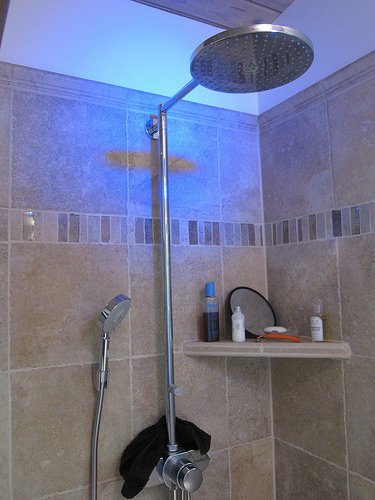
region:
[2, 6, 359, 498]
corner of a shower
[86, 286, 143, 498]
small movable shower head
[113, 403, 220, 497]
black washcloth on handle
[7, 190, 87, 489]
brown shower tile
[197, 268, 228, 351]
shower soap in the shower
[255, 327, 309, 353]
orange razor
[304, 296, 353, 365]
liquid shower soap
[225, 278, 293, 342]
small hand held mirror in the shower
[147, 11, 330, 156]
large shower head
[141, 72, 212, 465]
silver shower water pipes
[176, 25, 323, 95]
a large metal shower head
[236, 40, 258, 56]
tiny holes in the shower head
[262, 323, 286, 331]
a bar of white soap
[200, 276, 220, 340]
a plastic bottle of shampoo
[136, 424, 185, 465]
a black washcloth on the knob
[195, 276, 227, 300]
a blue top on the bottle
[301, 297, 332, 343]
a bottle of liquid soap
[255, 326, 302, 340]
an orange shaver on the shelf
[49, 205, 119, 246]
small granite tiles in the shower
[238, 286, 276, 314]
a round black mirror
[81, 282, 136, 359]
stainless steel shower head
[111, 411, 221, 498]
black washcloth hanging over shower knobs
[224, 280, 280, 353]
round mirror with black trim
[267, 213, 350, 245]
different color oblong tiles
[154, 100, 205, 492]
long pipe attached to shower knob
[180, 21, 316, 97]
large rainbow type shower head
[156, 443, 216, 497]
water knob for turning on water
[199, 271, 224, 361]
bottle with blue top sitting on shelf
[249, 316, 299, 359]
white soap sitting on shelf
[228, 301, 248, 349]
bottle part filled with white substance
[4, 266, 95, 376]
Tiles are brown color.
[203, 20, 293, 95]
Shower is silver color.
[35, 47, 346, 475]
Picture is taken in bathroom.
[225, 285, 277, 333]
One mirror is in stand.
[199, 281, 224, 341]
Shampoo is black color.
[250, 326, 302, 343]
Razor is orange color.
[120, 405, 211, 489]
Towel is black color.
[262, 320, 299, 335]
Soap is in dish.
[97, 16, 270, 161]
Bathroom light is on.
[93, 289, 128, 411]
Hand shower is silver color.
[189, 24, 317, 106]
a round silver shower head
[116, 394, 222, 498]
a used washcloth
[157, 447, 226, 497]
a silver round button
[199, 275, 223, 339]
a clear bottle with blue lid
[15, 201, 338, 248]
Small line of rectangle tiles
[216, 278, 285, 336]
a round black mirror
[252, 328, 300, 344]
an orange shaver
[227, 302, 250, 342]
a small bottle with white contents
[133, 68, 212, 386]
long silver piping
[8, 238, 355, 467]
large square tiles in the shower